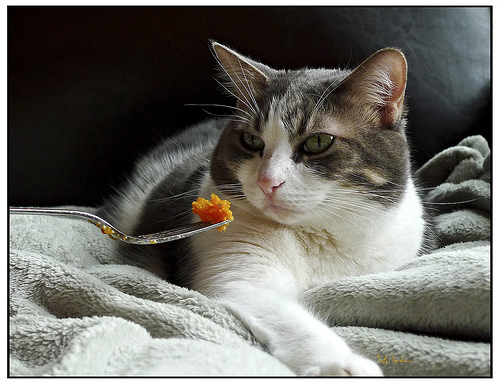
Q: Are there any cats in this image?
A: Yes, there is a cat.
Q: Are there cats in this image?
A: Yes, there is a cat.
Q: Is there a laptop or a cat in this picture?
A: Yes, there is a cat.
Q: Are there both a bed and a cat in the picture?
A: No, there is a cat but no beds.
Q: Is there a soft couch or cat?
A: Yes, there is a soft cat.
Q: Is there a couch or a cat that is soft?
A: Yes, the cat is soft.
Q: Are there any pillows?
A: No, there are no pillows.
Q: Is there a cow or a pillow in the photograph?
A: No, there are no pillows or cows.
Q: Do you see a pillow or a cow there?
A: No, there are no pillows or cows.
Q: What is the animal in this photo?
A: The animal is a cat.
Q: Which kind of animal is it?
A: The animal is a cat.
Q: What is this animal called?
A: This is a cat.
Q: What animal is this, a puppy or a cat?
A: This is a cat.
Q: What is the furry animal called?
A: The animal is a cat.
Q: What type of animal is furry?
A: The animal is a cat.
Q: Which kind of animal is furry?
A: The animal is a cat.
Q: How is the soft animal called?
A: The animal is a cat.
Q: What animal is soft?
A: The animal is a cat.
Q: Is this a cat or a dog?
A: This is a cat.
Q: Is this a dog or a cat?
A: This is a cat.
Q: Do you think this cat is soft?
A: Yes, the cat is soft.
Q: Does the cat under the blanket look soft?
A: Yes, the cat is soft.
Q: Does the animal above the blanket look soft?
A: Yes, the cat is soft.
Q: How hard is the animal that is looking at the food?
A: The cat is soft.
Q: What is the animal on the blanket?
A: The animal is a cat.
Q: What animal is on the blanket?
A: The animal is a cat.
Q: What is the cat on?
A: The cat is on the blanket.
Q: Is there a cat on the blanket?
A: Yes, there is a cat on the blanket.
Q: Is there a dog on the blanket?
A: No, there is a cat on the blanket.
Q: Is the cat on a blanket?
A: Yes, the cat is on a blanket.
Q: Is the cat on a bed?
A: No, the cat is on a blanket.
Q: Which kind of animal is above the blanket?
A: The animal is a cat.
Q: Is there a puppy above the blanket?
A: No, there is a cat above the blanket.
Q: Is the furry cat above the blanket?
A: Yes, the cat is above the blanket.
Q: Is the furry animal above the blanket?
A: Yes, the cat is above the blanket.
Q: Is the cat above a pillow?
A: No, the cat is above the blanket.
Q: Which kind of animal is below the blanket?
A: The animal is a cat.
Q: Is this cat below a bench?
A: No, the cat is below the blanket.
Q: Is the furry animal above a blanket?
A: No, the cat is below a blanket.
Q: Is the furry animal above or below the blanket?
A: The cat is below the blanket.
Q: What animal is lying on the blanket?
A: The cat is lying on the blanket.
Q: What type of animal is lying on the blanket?
A: The animal is a cat.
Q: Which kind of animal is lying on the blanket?
A: The animal is a cat.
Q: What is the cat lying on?
A: The cat is lying on the blanket.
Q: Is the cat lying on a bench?
A: No, the cat is lying on the blanket.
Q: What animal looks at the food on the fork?
A: The cat looks at the food.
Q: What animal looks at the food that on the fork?
A: The cat looks at the food.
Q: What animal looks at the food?
A: The cat looks at the food.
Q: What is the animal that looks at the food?
A: The animal is a cat.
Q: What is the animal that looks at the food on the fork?
A: The animal is a cat.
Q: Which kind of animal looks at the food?
A: The animal is a cat.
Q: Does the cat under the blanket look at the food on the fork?
A: Yes, the cat looks at the food.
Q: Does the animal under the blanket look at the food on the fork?
A: Yes, the cat looks at the food.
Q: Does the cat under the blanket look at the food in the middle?
A: Yes, the cat looks at the food.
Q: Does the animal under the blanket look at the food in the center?
A: Yes, the cat looks at the food.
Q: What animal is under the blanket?
A: The cat is under the blanket.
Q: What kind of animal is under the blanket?
A: The animal is a cat.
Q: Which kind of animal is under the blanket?
A: The animal is a cat.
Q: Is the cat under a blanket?
A: Yes, the cat is under a blanket.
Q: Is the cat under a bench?
A: No, the cat is under a blanket.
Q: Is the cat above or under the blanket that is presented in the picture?
A: The cat is under the blanket.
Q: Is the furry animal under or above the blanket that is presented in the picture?
A: The cat is under the blanket.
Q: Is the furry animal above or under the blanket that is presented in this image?
A: The cat is under the blanket.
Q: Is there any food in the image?
A: Yes, there is food.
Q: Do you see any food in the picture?
A: Yes, there is food.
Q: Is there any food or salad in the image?
A: Yes, there is food.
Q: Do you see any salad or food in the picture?
A: Yes, there is food.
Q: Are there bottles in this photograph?
A: No, there are no bottles.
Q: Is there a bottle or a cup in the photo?
A: No, there are no bottles or cups.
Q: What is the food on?
A: The food is on the fork.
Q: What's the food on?
A: The food is on the fork.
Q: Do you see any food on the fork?
A: Yes, there is food on the fork.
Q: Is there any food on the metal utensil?
A: Yes, there is food on the fork.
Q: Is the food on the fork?
A: Yes, the food is on the fork.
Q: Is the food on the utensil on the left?
A: Yes, the food is on the fork.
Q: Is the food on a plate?
A: No, the food is on the fork.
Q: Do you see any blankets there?
A: Yes, there is a blanket.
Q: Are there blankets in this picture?
A: Yes, there is a blanket.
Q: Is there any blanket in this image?
A: Yes, there is a blanket.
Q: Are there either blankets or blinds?
A: Yes, there is a blanket.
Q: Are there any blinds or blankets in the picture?
A: Yes, there is a blanket.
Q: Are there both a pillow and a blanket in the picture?
A: No, there is a blanket but no pillows.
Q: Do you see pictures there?
A: No, there are no pictures.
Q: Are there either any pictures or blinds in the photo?
A: No, there are no pictures or blinds.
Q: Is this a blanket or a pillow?
A: This is a blanket.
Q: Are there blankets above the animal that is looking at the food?
A: Yes, there is a blanket above the cat.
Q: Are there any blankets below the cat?
A: No, the blanket is above the cat.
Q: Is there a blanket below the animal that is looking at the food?
A: No, the blanket is above the cat.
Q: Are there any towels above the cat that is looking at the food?
A: No, there is a blanket above the cat.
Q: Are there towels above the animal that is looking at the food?
A: No, there is a blanket above the cat.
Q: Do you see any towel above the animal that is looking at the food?
A: No, there is a blanket above the cat.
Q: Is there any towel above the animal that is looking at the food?
A: No, there is a blanket above the cat.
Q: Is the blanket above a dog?
A: No, the blanket is above the cat.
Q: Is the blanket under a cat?
A: No, the blanket is above a cat.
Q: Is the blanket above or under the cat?
A: The blanket is above the cat.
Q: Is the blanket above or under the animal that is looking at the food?
A: The blanket is above the cat.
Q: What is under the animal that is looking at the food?
A: The blanket is under the cat.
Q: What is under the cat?
A: The blanket is under the cat.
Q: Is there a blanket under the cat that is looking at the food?
A: Yes, there is a blanket under the cat.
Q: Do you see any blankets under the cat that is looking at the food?
A: Yes, there is a blanket under the cat.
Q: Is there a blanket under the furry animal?
A: Yes, there is a blanket under the cat.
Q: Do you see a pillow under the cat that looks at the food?
A: No, there is a blanket under the cat.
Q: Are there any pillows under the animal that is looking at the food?
A: No, there is a blanket under the cat.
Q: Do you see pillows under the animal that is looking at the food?
A: No, there is a blanket under the cat.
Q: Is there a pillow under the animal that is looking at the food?
A: No, there is a blanket under the cat.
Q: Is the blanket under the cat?
A: Yes, the blanket is under the cat.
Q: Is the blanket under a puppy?
A: No, the blanket is under the cat.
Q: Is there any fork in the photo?
A: Yes, there is a fork.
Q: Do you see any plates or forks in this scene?
A: Yes, there is a fork.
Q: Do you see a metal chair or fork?
A: Yes, there is a metal fork.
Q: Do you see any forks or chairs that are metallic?
A: Yes, the fork is metallic.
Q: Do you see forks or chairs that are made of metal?
A: Yes, the fork is made of metal.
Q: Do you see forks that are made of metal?
A: Yes, there is a fork that is made of metal.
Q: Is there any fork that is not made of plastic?
A: Yes, there is a fork that is made of metal.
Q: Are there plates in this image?
A: No, there are no plates.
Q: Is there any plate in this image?
A: No, there are no plates.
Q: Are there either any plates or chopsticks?
A: No, there are no plates or chopsticks.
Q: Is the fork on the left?
A: Yes, the fork is on the left of the image.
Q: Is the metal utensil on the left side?
A: Yes, the fork is on the left of the image.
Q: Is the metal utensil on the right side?
A: No, the fork is on the left of the image.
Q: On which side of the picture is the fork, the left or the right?
A: The fork is on the left of the image.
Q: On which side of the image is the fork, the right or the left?
A: The fork is on the left of the image.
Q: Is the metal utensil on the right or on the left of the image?
A: The fork is on the left of the image.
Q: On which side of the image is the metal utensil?
A: The fork is on the left of the image.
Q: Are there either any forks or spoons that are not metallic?
A: No, there is a fork but it is metallic.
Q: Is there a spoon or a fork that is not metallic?
A: No, there is a fork but it is metallic.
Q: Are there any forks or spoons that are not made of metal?
A: No, there is a fork but it is made of metal.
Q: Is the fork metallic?
A: Yes, the fork is metallic.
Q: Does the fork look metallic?
A: Yes, the fork is metallic.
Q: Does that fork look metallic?
A: Yes, the fork is metallic.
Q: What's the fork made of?
A: The fork is made of metal.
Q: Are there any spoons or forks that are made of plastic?
A: No, there is a fork but it is made of metal.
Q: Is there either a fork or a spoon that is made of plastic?
A: No, there is a fork but it is made of metal.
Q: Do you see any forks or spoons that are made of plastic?
A: No, there is a fork but it is made of metal.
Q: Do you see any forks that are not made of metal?
A: No, there is a fork but it is made of metal.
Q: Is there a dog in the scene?
A: No, there are no dogs.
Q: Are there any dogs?
A: No, there are no dogs.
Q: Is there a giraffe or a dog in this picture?
A: No, there are no dogs or giraffes.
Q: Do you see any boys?
A: No, there are no boys.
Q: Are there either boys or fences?
A: No, there are no boys or fences.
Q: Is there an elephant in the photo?
A: No, there are no elephants.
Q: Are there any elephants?
A: No, there are no elephants.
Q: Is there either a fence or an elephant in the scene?
A: No, there are no elephants or fences.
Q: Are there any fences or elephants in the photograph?
A: No, there are no elephants or fences.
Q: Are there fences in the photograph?
A: No, there are no fences.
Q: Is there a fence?
A: No, there are no fences.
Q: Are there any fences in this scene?
A: No, there are no fences.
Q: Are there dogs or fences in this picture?
A: No, there are no fences or dogs.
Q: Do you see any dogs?
A: No, there are no dogs.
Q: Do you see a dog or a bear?
A: No, there are no dogs or bears.